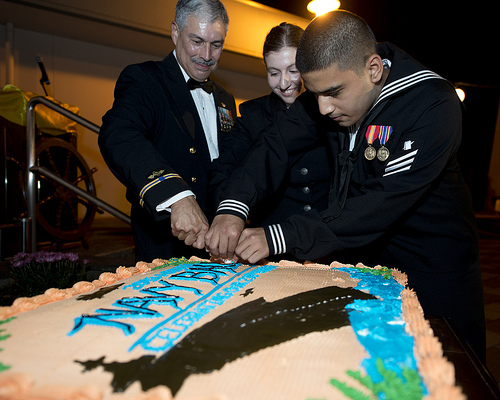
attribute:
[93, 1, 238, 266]
man — smiling, standing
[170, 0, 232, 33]
hair — gray, short, styled, neat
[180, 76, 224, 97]
tie — black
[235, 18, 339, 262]
woman — smiling, standing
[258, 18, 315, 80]
hair — neat, parted, brown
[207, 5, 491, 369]
man — standing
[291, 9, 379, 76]
hair — short, dark